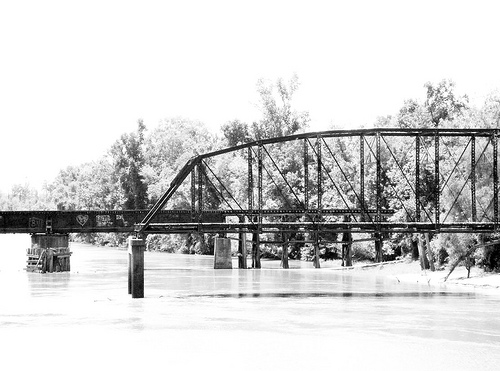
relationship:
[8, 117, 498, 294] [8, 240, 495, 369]
bridge crosses water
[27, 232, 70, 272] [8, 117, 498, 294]
column under bridge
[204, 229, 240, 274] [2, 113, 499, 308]
column under bridge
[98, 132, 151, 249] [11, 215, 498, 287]
trees under shore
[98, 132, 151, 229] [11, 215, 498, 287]
trees under shore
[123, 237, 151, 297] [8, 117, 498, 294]
column beside bridge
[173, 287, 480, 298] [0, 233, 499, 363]
reflection in water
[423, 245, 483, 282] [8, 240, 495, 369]
branch hanging in water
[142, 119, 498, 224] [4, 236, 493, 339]
trellis over water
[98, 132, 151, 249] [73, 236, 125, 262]
trees along riverbank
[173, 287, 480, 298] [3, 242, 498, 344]
reflection in water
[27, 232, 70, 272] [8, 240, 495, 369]
column in water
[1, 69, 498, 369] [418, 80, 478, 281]
snow on tree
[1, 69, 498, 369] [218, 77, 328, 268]
snow on tree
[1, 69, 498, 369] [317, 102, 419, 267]
snow on tree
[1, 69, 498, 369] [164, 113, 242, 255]
snow on tree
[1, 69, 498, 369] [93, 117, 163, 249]
snow on tree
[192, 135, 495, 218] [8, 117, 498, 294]
fence on bridge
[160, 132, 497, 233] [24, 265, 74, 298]
bridge has reflection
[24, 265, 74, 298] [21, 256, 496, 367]
reflection in water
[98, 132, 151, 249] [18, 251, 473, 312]
trees are on riverbank